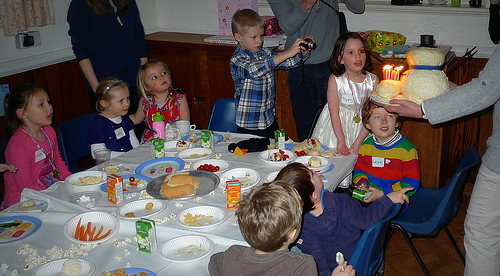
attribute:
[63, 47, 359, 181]
children — partying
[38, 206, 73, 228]
cloth — white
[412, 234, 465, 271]
floor — brown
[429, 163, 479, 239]
chair — blue, plastic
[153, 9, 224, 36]
wall — white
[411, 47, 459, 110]
cake — white, snowman, birthday, styled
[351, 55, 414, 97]
candles — lit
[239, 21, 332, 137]
boy — taking, little, sitting, clad, holding, wearing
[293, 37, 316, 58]
camera — black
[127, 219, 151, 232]
box — small, green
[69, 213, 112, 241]
carrots — sliced, stripped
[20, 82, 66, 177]
girl — little, young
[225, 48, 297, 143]
shirt — plaid, pink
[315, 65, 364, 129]
dress — sleeveless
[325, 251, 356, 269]
spoon — plastic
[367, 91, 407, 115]
platter — silver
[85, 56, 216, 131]
girls — partygoers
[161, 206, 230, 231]
plate — white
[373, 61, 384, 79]
candle — lit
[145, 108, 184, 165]
bottle — pink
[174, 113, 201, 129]
mug — white